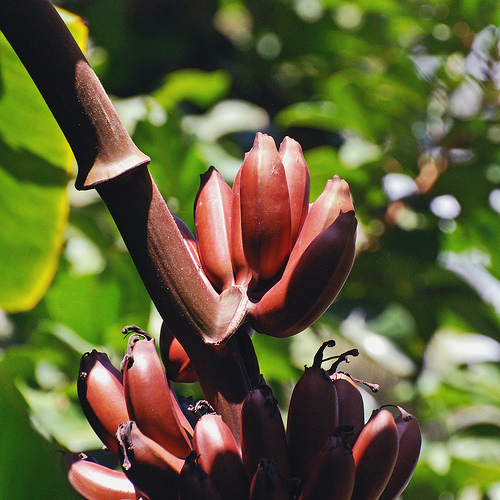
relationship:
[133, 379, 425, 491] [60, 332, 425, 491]
shadow on banana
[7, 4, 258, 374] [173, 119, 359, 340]
branch with bananas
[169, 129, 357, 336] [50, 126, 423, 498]
fruit in cluster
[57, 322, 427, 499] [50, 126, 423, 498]
fruit in cluster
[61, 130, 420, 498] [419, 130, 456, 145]
bananas above ground